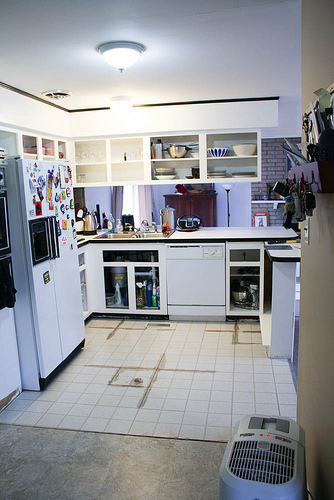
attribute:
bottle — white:
[99, 277, 133, 309]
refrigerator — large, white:
[8, 155, 103, 369]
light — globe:
[95, 38, 145, 74]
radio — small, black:
[177, 216, 201, 229]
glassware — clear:
[75, 144, 104, 162]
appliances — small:
[151, 135, 199, 156]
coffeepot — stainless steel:
[79, 212, 97, 235]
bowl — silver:
[161, 142, 197, 161]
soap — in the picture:
[110, 284, 124, 298]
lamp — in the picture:
[219, 183, 234, 227]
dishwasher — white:
[167, 223, 227, 330]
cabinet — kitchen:
[144, 132, 264, 185]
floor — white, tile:
[4, 312, 280, 496]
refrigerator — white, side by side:
[3, 152, 86, 392]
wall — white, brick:
[264, 145, 280, 182]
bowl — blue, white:
[206, 146, 228, 156]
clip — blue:
[47, 169, 53, 176]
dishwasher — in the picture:
[171, 243, 227, 312]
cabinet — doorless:
[97, 248, 159, 310]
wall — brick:
[250, 141, 305, 230]